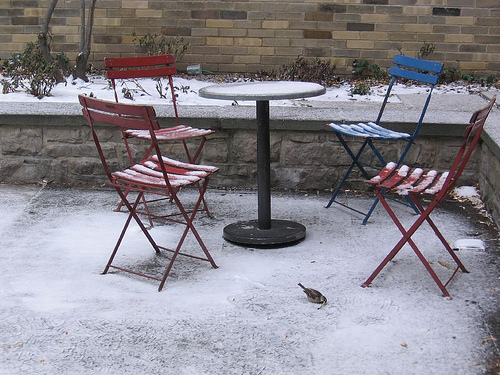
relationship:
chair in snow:
[348, 77, 499, 308] [95, 194, 438, 355]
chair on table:
[348, 77, 499, 308] [195, 65, 332, 264]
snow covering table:
[195, 289, 300, 367] [195, 65, 332, 264]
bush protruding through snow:
[0, 49, 61, 98] [2, 71, 484, 101]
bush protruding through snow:
[125, 27, 190, 100] [2, 71, 484, 101]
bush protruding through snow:
[258, 53, 341, 88] [2, 71, 484, 101]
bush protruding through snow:
[346, 80, 374, 96] [2, 71, 484, 101]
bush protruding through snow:
[391, 42, 434, 84] [2, 71, 484, 101]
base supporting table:
[224, 216, 311, 248] [198, 79, 325, 247]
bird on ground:
[297, 278, 331, 310] [270, 276, 371, 326]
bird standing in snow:
[297, 278, 331, 310] [233, 296, 440, 345]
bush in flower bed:
[0, 28, 66, 98] [0, 70, 495, 97]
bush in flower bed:
[125, 27, 190, 100] [0, 70, 495, 97]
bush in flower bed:
[304, 45, 342, 88] [0, 70, 495, 97]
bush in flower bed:
[346, 80, 374, 96] [0, 70, 495, 97]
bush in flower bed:
[391, 42, 434, 84] [0, 70, 495, 97]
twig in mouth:
[315, 300, 327, 311] [320, 297, 327, 304]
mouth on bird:
[320, 297, 327, 304] [297, 280, 329, 307]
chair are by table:
[77, 93, 222, 291] [198, 79, 325, 247]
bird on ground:
[297, 278, 331, 310] [0, 181, 497, 373]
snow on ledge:
[0, 184, 499, 372] [3, 78, 195, 120]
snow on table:
[0, 184, 499, 372] [198, 79, 325, 247]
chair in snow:
[77, 93, 222, 291] [31, 267, 451, 360]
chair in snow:
[339, 27, 495, 322] [261, 273, 475, 358]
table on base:
[198, 79, 325, 247] [220, 218, 309, 250]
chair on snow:
[107, 51, 216, 152] [80, 204, 262, 272]